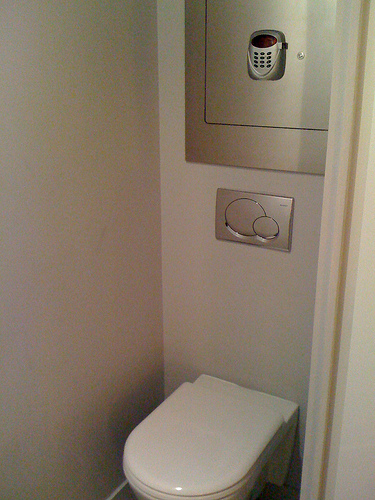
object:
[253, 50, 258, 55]
button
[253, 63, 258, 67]
button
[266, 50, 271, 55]
button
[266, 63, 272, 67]
button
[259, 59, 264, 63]
button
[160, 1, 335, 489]
wall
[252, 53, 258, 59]
button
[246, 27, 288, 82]
cell phone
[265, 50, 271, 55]
button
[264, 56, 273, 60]
button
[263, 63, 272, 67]
button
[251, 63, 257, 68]
button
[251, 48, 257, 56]
button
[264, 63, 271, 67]
button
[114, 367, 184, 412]
shadow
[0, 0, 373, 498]
bathroom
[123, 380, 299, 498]
lid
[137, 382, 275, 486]
sink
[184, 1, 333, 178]
safe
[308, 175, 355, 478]
frame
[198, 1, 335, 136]
door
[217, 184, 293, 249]
flush button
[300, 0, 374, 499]
white curtain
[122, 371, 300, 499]
toilet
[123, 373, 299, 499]
bathroom toilet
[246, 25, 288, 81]
keypad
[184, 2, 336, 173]
wall safe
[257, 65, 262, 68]
button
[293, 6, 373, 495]
door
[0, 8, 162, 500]
wall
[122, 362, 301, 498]
top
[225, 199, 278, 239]
plate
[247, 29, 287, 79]
device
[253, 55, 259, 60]
button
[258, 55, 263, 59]
button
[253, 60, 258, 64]
button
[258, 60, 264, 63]
button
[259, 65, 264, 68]
button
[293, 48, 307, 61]
circle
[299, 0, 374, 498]
frame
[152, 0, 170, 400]
corner